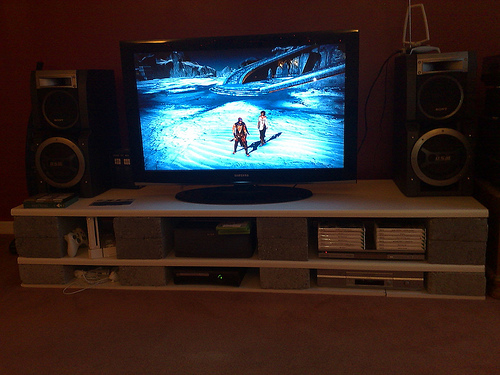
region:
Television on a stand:
[117, 27, 362, 204]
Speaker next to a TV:
[392, 48, 479, 196]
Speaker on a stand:
[25, 64, 117, 191]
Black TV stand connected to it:
[175, 184, 311, 202]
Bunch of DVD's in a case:
[315, 220, 426, 253]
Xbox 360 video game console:
[171, 268, 243, 287]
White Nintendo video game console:
[83, 215, 103, 258]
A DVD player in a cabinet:
[314, 270, 428, 292]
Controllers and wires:
[61, 266, 119, 291]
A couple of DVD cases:
[22, 190, 77, 207]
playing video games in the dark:
[23, 13, 485, 343]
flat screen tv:
[111, 22, 383, 227]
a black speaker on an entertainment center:
[373, 24, 476, 244]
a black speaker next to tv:
[16, 45, 146, 231]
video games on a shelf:
[308, 212, 474, 289]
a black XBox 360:
[156, 259, 298, 319]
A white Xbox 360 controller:
[54, 220, 144, 300]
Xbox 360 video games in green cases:
[168, 214, 303, 266]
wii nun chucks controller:
[50, 265, 161, 305]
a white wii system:
[74, 208, 150, 303]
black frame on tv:
[122, 31, 343, 171]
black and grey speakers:
[379, 33, 497, 227]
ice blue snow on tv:
[147, 67, 343, 169]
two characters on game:
[194, 96, 277, 156]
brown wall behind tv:
[344, 3, 379, 70]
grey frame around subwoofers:
[33, 130, 77, 196]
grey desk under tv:
[72, 185, 494, 227]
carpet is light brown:
[20, 306, 223, 367]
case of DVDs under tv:
[305, 212, 445, 289]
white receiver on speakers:
[380, 0, 436, 59]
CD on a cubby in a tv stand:
[375, 225, 425, 232]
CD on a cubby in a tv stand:
[319, 243, 363, 249]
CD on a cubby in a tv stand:
[319, 238, 365, 244]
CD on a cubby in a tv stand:
[318, 231, 368, 238]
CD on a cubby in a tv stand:
[314, 225, 366, 232]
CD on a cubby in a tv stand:
[376, 245, 426, 254]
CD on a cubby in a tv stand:
[377, 242, 424, 249]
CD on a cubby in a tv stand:
[373, 236, 426, 242]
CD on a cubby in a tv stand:
[375, 231, 425, 237]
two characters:
[221, 99, 297, 159]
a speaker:
[31, 67, 98, 183]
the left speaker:
[406, 60, 476, 191]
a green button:
[211, 272, 226, 284]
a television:
[123, 47, 350, 173]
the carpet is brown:
[226, 319, 293, 364]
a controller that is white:
[65, 228, 85, 253]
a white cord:
[60, 277, 77, 297]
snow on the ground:
[162, 118, 212, 154]